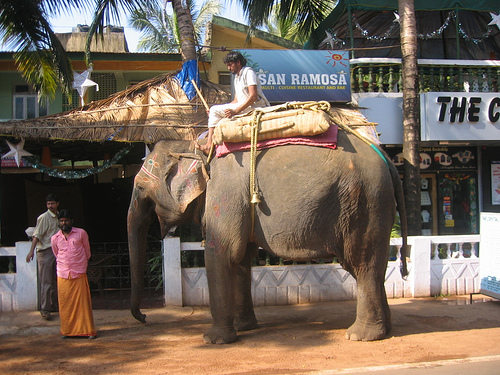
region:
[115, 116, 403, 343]
Elephant standing in front of store.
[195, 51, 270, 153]
Man sitting on top of elephant.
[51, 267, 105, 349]
Man wearing an orange mundu.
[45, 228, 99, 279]
Man dressed in a pink shirt.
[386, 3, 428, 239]
Trunk of palm tree growing in front of store.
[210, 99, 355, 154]
Package tied on elephant's back.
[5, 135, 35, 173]
White star hanging front ceiling.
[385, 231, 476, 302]
White fence in front of store.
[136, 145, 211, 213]
Painted designs on elephant's head and ear.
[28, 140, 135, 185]
Silver tinsel hanging from ceiling.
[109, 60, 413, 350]
elephant standing in front of building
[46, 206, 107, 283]
man in pink shirt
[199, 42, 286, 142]
man sitting on elephant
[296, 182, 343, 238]
wrinkles on elephant skin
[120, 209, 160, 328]
hanging trunk of elephant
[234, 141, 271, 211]
rope on side of elephant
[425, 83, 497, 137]
letters on building face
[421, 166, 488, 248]
front door of business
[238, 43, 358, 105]
blue sign with white lettering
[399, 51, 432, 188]
trunk of palm tree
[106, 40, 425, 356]
Elephant is brown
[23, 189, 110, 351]
Two man in front of elephant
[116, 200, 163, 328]
Big trunk of elephant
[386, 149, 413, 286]
Tail of elephant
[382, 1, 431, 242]
Trunk of palm in front of building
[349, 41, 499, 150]
Building has balcony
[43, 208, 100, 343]
Man wears pink shirt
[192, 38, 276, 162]
Man sits on back of elephant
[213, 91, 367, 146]
Big cushion on back of elephant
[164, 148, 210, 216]
Big ear is painted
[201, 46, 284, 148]
A man on top of a elephant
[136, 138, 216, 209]
Decorations painted on an elephant's head and ear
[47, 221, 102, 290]
A man in a pink shirt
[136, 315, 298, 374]
Brown dusty ground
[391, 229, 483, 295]
A white decorative wall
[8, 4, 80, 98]
Leaves on a palm tree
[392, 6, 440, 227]
A tall slim tree trunk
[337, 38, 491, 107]
The balcony of a bar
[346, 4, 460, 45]
Loops of tinsel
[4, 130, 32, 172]
A silver star hanging down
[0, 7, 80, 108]
a tree in a distance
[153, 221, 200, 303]
a tree in a distance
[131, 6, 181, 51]
a tree in a distance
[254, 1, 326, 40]
a tree in a distance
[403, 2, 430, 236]
a tree in a distance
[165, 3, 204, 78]
a tree in a distance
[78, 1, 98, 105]
a tree in a distance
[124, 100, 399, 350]
a huge elephant